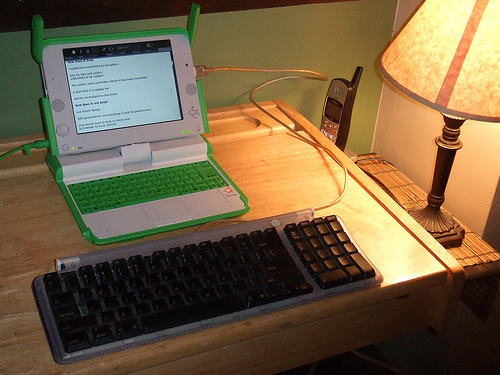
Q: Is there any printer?
A: No, there are no printers.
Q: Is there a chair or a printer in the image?
A: No, there are no printers or chairs.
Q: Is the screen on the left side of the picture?
A: Yes, the screen is on the left of the image.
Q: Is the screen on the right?
A: No, the screen is on the left of the image.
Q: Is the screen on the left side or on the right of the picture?
A: The screen is on the left of the image.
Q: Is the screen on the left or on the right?
A: The screen is on the left of the image.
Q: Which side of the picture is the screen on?
A: The screen is on the left of the image.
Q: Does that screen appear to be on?
A: Yes, the screen is on.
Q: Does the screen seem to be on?
A: Yes, the screen is on.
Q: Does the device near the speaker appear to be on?
A: Yes, the screen is on.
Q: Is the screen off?
A: No, the screen is on.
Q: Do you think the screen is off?
A: No, the screen is on.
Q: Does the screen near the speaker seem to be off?
A: No, the screen is on.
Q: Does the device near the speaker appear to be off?
A: No, the screen is on.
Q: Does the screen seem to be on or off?
A: The screen is on.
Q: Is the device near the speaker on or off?
A: The screen is on.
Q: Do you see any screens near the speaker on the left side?
A: Yes, there is a screen near the speaker.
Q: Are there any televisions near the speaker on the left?
A: No, there is a screen near the speaker.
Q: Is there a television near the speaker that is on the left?
A: No, there is a screen near the speaker.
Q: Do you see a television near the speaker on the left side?
A: No, there is a screen near the speaker.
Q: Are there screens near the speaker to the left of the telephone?
A: Yes, there is a screen near the speaker.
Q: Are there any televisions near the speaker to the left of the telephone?
A: No, there is a screen near the speaker.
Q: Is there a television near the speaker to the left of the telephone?
A: No, there is a screen near the speaker.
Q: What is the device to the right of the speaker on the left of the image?
A: The device is a screen.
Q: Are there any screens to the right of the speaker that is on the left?
A: Yes, there is a screen to the right of the speaker.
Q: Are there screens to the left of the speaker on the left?
A: No, the screen is to the right of the speaker.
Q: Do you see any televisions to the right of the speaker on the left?
A: No, there is a screen to the right of the speaker.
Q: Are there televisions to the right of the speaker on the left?
A: No, there is a screen to the right of the speaker.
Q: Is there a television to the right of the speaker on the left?
A: No, there is a screen to the right of the speaker.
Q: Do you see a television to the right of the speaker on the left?
A: No, there is a screen to the right of the speaker.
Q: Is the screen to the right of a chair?
A: No, the screen is to the right of a speaker.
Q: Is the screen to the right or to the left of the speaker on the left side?
A: The screen is to the right of the speaker.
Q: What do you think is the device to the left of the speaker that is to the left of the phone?
A: The device is a screen.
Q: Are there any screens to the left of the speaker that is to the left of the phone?
A: Yes, there is a screen to the left of the speaker.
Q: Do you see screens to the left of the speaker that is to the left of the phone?
A: Yes, there is a screen to the left of the speaker.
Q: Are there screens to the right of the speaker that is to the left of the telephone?
A: No, the screen is to the left of the speaker.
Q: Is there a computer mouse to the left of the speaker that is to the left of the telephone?
A: No, there is a screen to the left of the speaker.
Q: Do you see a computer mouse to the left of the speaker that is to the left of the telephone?
A: No, there is a screen to the left of the speaker.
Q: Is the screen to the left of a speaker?
A: Yes, the screen is to the left of a speaker.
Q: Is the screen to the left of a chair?
A: No, the screen is to the left of a speaker.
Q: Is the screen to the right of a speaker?
A: No, the screen is to the left of a speaker.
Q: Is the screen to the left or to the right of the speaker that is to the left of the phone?
A: The screen is to the left of the speaker.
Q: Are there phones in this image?
A: Yes, there is a phone.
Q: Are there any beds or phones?
A: Yes, there is a phone.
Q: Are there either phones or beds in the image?
A: Yes, there is a phone.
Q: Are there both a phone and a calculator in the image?
A: No, there is a phone but no calculators.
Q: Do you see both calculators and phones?
A: No, there is a phone but no calculators.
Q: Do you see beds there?
A: No, there are no beds.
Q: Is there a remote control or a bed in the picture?
A: No, there are no beds or remote controls.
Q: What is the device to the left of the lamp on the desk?
A: The device is a phone.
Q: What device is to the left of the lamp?
A: The device is a phone.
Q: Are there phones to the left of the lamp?
A: Yes, there is a phone to the left of the lamp.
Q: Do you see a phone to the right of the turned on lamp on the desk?
A: No, the phone is to the left of the lamp.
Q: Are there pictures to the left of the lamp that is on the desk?
A: No, there is a phone to the left of the lamp.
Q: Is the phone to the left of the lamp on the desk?
A: Yes, the phone is to the left of the lamp.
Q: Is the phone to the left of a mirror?
A: No, the phone is to the left of the lamp.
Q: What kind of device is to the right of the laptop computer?
A: The device is a phone.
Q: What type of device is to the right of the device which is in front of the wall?
A: The device is a phone.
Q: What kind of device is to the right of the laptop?
A: The device is a phone.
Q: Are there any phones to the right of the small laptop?
A: Yes, there is a phone to the right of the laptop.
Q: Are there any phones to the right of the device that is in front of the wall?
A: Yes, there is a phone to the right of the laptop.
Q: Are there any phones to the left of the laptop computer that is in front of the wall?
A: No, the phone is to the right of the laptop computer.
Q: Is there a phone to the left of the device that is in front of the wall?
A: No, the phone is to the right of the laptop computer.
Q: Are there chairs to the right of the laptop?
A: No, there is a phone to the right of the laptop.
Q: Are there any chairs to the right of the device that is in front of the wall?
A: No, there is a phone to the right of the laptop.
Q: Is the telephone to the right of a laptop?
A: Yes, the telephone is to the right of a laptop.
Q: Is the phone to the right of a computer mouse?
A: No, the phone is to the right of a laptop.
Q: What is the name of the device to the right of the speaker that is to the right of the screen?
A: The device is a phone.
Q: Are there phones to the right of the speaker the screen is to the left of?
A: Yes, there is a phone to the right of the speaker.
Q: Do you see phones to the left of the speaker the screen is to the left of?
A: No, the phone is to the right of the speaker.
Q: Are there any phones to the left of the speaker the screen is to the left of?
A: No, the phone is to the right of the speaker.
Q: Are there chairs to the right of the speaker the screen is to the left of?
A: No, there is a phone to the right of the speaker.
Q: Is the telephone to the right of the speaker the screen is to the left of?
A: Yes, the telephone is to the right of the speaker.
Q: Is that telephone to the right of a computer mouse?
A: No, the telephone is to the right of the speaker.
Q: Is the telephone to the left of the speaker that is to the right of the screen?
A: No, the telephone is to the right of the speaker.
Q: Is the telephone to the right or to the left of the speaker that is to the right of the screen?
A: The telephone is to the right of the speaker.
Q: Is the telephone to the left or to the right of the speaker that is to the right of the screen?
A: The telephone is to the right of the speaker.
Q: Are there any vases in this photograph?
A: No, there are no vases.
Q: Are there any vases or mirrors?
A: No, there are no vases or mirrors.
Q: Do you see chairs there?
A: No, there are no chairs.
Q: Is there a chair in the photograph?
A: No, there are no chairs.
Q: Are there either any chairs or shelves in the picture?
A: No, there are no chairs or shelves.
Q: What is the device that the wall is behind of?
A: The device is a laptop.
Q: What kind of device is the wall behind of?
A: The wall is behind the laptop.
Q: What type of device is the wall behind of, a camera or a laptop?
A: The wall is behind a laptop.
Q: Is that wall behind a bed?
A: No, the wall is behind the laptop.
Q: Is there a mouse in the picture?
A: No, there are no computer mice.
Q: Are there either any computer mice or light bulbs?
A: No, there are no computer mice or light bulbs.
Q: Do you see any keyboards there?
A: Yes, there is a keyboard.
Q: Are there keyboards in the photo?
A: Yes, there is a keyboard.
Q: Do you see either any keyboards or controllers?
A: Yes, there is a keyboard.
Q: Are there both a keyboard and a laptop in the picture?
A: Yes, there are both a keyboard and a laptop.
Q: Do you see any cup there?
A: No, there are no cups.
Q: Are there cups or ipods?
A: No, there are no cups or ipods.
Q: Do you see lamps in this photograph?
A: Yes, there is a lamp.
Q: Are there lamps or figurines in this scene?
A: Yes, there is a lamp.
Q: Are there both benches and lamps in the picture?
A: No, there is a lamp but no benches.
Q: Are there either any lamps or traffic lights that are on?
A: Yes, the lamp is on.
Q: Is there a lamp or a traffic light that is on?
A: Yes, the lamp is on.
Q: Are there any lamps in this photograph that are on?
A: Yes, there is a lamp that is on.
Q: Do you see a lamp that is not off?
A: Yes, there is a lamp that is on .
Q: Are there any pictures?
A: No, there are no pictures.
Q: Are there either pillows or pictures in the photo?
A: No, there are no pictures or pillows.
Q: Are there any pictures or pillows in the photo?
A: No, there are no pictures or pillows.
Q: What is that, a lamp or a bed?
A: That is a lamp.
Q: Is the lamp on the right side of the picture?
A: Yes, the lamp is on the right of the image.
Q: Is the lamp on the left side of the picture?
A: No, the lamp is on the right of the image.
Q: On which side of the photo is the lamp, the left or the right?
A: The lamp is on the right of the image.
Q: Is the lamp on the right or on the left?
A: The lamp is on the right of the image.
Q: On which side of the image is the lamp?
A: The lamp is on the right of the image.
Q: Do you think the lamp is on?
A: Yes, the lamp is on.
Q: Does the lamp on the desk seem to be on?
A: Yes, the lamp is on.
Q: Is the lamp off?
A: No, the lamp is on.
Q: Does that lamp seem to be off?
A: No, the lamp is on.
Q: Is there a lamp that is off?
A: No, there is a lamp but it is on.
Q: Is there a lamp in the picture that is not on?
A: No, there is a lamp but it is on.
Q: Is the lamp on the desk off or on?
A: The lamp is on.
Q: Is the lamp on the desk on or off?
A: The lamp is on.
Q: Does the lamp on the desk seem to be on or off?
A: The lamp is on.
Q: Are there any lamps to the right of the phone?
A: Yes, there is a lamp to the right of the phone.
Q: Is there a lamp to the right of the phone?
A: Yes, there is a lamp to the right of the phone.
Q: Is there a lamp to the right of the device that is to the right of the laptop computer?
A: Yes, there is a lamp to the right of the phone.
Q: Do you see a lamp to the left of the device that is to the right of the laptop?
A: No, the lamp is to the right of the telephone.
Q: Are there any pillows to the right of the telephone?
A: No, there is a lamp to the right of the telephone.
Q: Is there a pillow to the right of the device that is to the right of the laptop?
A: No, there is a lamp to the right of the telephone.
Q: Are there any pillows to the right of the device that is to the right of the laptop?
A: No, there is a lamp to the right of the telephone.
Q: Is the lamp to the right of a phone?
A: Yes, the lamp is to the right of a phone.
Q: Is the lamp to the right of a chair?
A: No, the lamp is to the right of a phone.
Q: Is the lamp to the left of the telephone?
A: No, the lamp is to the right of the telephone.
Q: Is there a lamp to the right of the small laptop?
A: Yes, there is a lamp to the right of the laptop.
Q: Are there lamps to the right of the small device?
A: Yes, there is a lamp to the right of the laptop.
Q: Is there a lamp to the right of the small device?
A: Yes, there is a lamp to the right of the laptop.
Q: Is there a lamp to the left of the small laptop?
A: No, the lamp is to the right of the laptop.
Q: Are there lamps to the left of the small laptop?
A: No, the lamp is to the right of the laptop.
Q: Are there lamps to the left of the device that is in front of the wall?
A: No, the lamp is to the right of the laptop.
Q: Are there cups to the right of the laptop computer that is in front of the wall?
A: No, there is a lamp to the right of the laptop.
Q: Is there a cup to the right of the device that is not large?
A: No, there is a lamp to the right of the laptop.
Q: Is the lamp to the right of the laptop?
A: Yes, the lamp is to the right of the laptop.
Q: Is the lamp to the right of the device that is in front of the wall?
A: Yes, the lamp is to the right of the laptop.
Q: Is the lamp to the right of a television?
A: No, the lamp is to the right of the laptop.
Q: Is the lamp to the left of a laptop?
A: No, the lamp is to the right of a laptop.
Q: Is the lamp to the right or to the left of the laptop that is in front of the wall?
A: The lamp is to the right of the laptop.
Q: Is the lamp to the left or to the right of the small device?
A: The lamp is to the right of the laptop.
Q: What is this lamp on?
A: The lamp is on the desk.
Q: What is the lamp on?
A: The lamp is on the desk.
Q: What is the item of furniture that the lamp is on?
A: The piece of furniture is a desk.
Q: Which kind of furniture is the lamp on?
A: The lamp is on the desk.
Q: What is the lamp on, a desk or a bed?
A: The lamp is on a desk.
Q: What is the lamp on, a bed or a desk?
A: The lamp is on a desk.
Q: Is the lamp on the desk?
A: Yes, the lamp is on the desk.